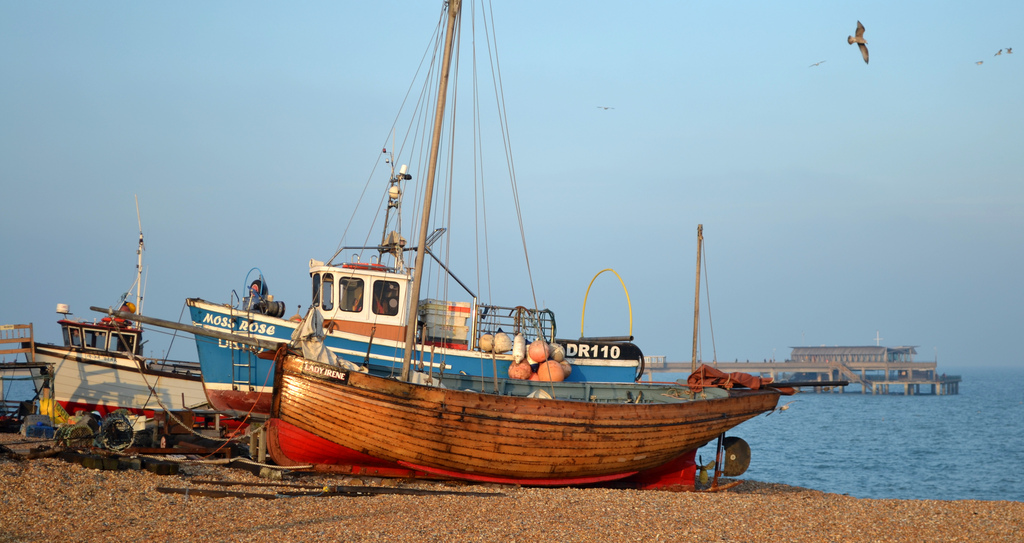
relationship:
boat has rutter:
[187, 261, 783, 487] [700, 425, 765, 484]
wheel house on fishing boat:
[52, 307, 146, 360] [19, 296, 223, 449]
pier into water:
[659, 332, 982, 402] [4, 366, 1022, 503]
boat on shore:
[187, 261, 783, 487] [0, 432, 1022, 537]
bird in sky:
[838, 11, 890, 74] [0, 4, 1022, 365]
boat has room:
[187, 261, 783, 487] [313, 257, 420, 350]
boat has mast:
[187, 261, 783, 487] [393, 2, 469, 337]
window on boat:
[311, 268, 398, 308] [187, 261, 783, 487]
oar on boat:
[378, 345, 502, 382] [187, 261, 783, 487]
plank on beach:
[142, 463, 367, 511] [0, 415, 1024, 536]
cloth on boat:
[665, 351, 836, 431] [187, 261, 783, 487]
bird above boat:
[848, 21, 872, 64] [187, 261, 783, 487]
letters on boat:
[555, 331, 629, 360] [187, 261, 783, 487]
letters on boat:
[565, 343, 620, 359] [187, 261, 783, 487]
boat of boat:
[187, 261, 783, 487] [178, 242, 733, 480]